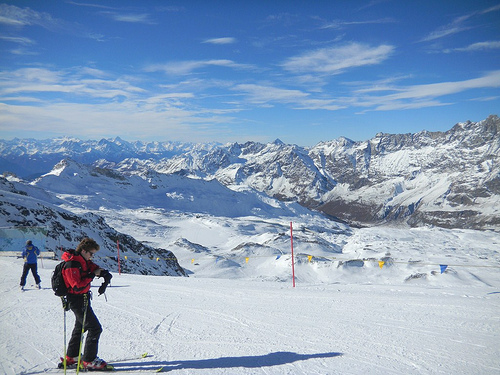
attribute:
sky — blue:
[197, 28, 367, 135]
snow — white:
[343, 307, 422, 368]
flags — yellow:
[125, 250, 392, 279]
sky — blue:
[0, 3, 496, 150]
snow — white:
[324, 304, 452, 359]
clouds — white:
[17, 67, 427, 129]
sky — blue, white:
[9, 2, 480, 142]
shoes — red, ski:
[59, 0, 109, 23]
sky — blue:
[224, 5, 341, 103]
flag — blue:
[439, 262, 449, 273]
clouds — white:
[438, 44, 465, 92]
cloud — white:
[283, 37, 393, 77]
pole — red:
[286, 215, 300, 285]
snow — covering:
[187, 295, 494, 374]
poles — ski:
[58, 291, 92, 371]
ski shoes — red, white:
[57, 347, 163, 374]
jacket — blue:
[22, 248, 40, 263]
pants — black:
[19, 264, 44, 285]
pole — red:
[288, 220, 295, 287]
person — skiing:
[16, 235, 44, 290]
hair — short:
[75, 235, 102, 252]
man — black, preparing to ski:
[50, 232, 114, 372]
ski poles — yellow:
[47, 283, 118, 371]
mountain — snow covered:
[236, 138, 338, 198]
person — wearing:
[45, 238, 130, 368]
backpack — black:
[43, 252, 73, 300]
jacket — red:
[57, 244, 102, 296]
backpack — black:
[52, 257, 93, 298]